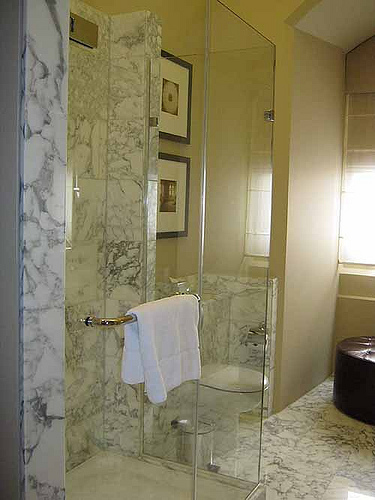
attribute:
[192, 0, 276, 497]
door — sliding, glass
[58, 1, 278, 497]
shower —  glass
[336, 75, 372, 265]
window — Brightly, lit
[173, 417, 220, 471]
trash can — metal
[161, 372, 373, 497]
marble floor — white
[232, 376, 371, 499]
floor — marble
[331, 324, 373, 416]
seat — leather, ottoman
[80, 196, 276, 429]
shower — glass, enclosed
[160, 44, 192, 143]
painting — framed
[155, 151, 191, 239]
painting — framed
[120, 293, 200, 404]
towel — white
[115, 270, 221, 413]
towel — white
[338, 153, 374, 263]
window — frosted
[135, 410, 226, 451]
wastebasket — small, metal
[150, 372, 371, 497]
floor — marble, tiled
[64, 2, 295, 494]
shower — tiled, marble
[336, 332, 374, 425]
seat — brown, leather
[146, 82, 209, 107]
wall — white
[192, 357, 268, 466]
toilet — white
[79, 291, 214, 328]
bar — metal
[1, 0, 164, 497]
wall — stoned, tiled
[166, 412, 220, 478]
trash can — chrome